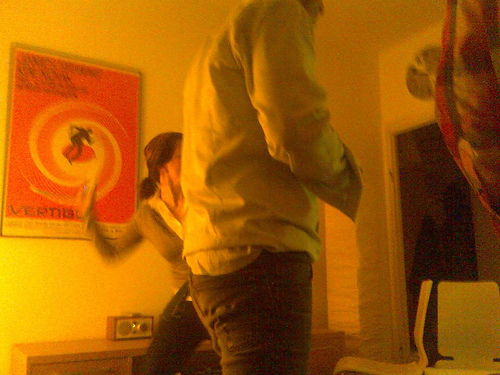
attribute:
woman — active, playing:
[80, 131, 210, 374]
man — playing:
[179, 1, 362, 373]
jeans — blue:
[187, 249, 313, 374]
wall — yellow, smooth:
[0, 0, 496, 374]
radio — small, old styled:
[106, 314, 153, 339]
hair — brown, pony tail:
[135, 131, 182, 198]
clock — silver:
[405, 47, 440, 100]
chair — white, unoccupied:
[334, 281, 433, 374]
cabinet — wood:
[12, 330, 346, 372]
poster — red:
[2, 44, 142, 241]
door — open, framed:
[395, 121, 476, 364]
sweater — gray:
[83, 199, 193, 287]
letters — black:
[10, 52, 98, 223]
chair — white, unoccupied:
[424, 280, 498, 373]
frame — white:
[383, 112, 434, 359]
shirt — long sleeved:
[183, 0, 363, 278]